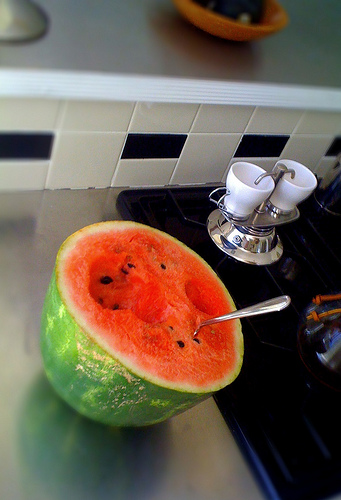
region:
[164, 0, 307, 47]
orange bowl on counter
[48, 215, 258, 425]
half of green and juicy red watermelon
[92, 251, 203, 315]
juicy red watermelon halve with small black seeds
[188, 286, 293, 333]
silver spoon stuck in red watermelon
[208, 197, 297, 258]
small silver espressor order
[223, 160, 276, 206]
small white cup on machine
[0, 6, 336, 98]
three and a half black tiles visible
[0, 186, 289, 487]
stainless steel counter tops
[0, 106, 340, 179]
black and white ceramic tile in backsplash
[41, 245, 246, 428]
some people wearing gas madkblack shiny metal tray reflectiog people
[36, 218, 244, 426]
Half of a watermelon.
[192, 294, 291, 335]
Part of a spoon.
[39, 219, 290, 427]
A watermelon with a spoon in it.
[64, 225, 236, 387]
Red part of a watermelon.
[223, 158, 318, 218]
Two white cups on a sink.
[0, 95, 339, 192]
Tile on a wall.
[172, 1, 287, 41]
Part of a bowl.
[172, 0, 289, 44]
A brown wood bowl.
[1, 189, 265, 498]
A stainless steel counter.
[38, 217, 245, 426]
Watermelon on a counter.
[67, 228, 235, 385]
Red watermelon fruit.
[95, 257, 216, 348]
Black seeds in the watermelon.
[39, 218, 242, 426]
The green rind of a watermelon.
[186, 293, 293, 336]
A silver spoon poked into the watermelon.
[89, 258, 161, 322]
Scoops taken out of the watermelon fruit.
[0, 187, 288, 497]
Half of a melon on a metal countertop.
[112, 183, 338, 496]
A black tray next to the watermelon.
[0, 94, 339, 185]
Tan and black tiles along the wall.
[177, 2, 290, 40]
A wooden bowl on a shelf.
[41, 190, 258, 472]
large watermelon on counter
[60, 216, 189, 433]
watermelon has been halved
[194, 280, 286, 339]
steel spoon in watermelon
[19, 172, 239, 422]
pink center of watermelon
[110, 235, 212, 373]
black seeds in watermelon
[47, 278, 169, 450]
green rind of watermelon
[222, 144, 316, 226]
two white espresso cups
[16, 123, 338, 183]
black tile on backsplash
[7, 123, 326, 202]
white tile on backsplash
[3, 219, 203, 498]
steel counter under watermelon